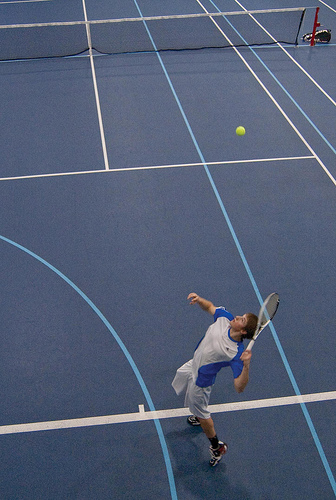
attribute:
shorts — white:
[168, 360, 215, 421]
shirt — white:
[193, 304, 245, 388]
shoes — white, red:
[180, 406, 234, 472]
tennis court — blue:
[2, 2, 334, 498]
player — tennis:
[151, 271, 296, 467]